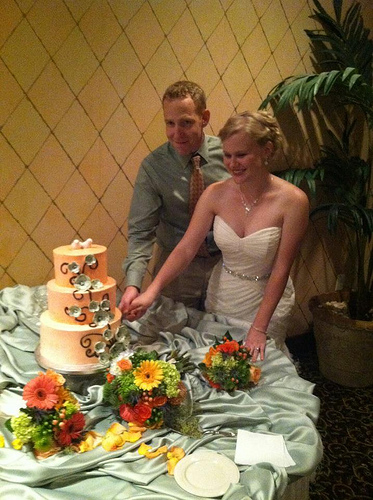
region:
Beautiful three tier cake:
[26, 229, 145, 377]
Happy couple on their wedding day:
[113, 78, 335, 356]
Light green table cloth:
[1, 270, 324, 498]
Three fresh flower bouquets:
[4, 337, 297, 449]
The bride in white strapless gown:
[130, 98, 316, 342]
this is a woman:
[168, 57, 325, 407]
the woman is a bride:
[118, 105, 329, 393]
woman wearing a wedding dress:
[120, 113, 321, 388]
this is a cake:
[17, 213, 150, 410]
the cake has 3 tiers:
[24, 206, 161, 398]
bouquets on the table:
[6, 317, 284, 487]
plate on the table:
[153, 443, 258, 498]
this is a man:
[96, 64, 238, 330]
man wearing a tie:
[169, 149, 216, 272]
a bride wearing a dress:
[189, 121, 371, 405]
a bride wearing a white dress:
[194, 131, 362, 401]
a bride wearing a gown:
[212, 105, 330, 367]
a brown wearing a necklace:
[194, 108, 321, 328]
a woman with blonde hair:
[213, 89, 303, 264]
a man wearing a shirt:
[133, 75, 218, 253]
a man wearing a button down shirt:
[135, 68, 300, 314]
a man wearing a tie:
[126, 84, 290, 314]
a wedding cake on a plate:
[4, 224, 218, 421]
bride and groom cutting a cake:
[33, 78, 312, 374]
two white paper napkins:
[233, 423, 296, 470]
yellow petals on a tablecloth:
[78, 418, 185, 476]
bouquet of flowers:
[4, 369, 83, 454]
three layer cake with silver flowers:
[36, 237, 132, 369]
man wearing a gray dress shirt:
[117, 81, 230, 314]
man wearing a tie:
[117, 78, 232, 316]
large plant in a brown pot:
[259, 0, 371, 392]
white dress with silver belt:
[203, 212, 296, 352]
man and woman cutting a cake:
[113, 258, 140, 338]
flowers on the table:
[107, 344, 192, 434]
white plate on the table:
[168, 444, 234, 497]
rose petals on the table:
[87, 420, 180, 476]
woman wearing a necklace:
[231, 185, 277, 220]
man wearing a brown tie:
[186, 158, 208, 205]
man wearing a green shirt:
[123, 135, 253, 247]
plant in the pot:
[277, 46, 364, 318]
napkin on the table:
[223, 415, 308, 482]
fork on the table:
[193, 411, 243, 448]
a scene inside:
[4, 5, 362, 499]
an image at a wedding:
[12, 11, 353, 495]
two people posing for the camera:
[111, 43, 317, 436]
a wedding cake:
[27, 182, 151, 428]